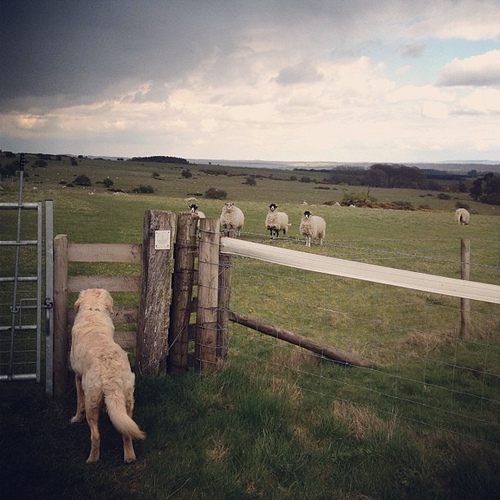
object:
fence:
[50, 201, 470, 442]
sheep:
[188, 202, 472, 247]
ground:
[399, 157, 465, 186]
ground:
[198, 376, 500, 499]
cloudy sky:
[0, 0, 499, 162]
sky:
[0, 0, 499, 165]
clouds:
[0, 2, 498, 164]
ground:
[363, 91, 383, 114]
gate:
[0, 169, 499, 447]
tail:
[103, 380, 148, 441]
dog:
[70, 288, 147, 464]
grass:
[0, 181, 497, 497]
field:
[0, 151, 497, 497]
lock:
[44, 298, 52, 335]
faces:
[269, 203, 310, 217]